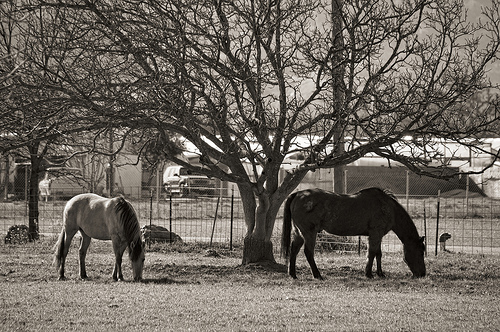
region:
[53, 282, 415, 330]
The grass on the ground is short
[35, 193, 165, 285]
The horse is eating grass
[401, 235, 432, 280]
The head of the horse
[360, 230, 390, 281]
The front legs of the horse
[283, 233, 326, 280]
The back legs of the horse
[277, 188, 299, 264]
The tail of the horse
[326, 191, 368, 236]
The stomach of the horse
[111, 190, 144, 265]
The mane of the horse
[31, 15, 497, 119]
The tree is large with no leaves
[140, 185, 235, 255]
The fence is made of metal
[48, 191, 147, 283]
light grey horse grazing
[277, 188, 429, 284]
dark brown horse grazing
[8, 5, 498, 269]
tree bare of leaves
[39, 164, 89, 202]
white pick up truck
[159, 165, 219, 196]
dark sport utility vehicle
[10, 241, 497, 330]
green grass in meadow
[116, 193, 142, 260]
dark hair on mane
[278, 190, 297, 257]
long dark horse hair tail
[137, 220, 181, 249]
boulder at grass edge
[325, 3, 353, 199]
tall flag pole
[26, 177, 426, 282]
two horses in field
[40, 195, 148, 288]
white horse in field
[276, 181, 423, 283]
dark horse in field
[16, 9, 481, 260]
tree with leafless branches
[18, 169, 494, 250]
fence behind the horses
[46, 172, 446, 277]
two horses grazing on grass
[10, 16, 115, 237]
tree on left side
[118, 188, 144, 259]
dark hair of white horse's mane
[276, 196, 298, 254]
dark hair of dark horse's tail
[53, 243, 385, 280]
legs of two horses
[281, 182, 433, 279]
a black horse grazing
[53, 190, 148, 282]
a grey horse grazing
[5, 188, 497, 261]
a long metal fence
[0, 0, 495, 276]
a large bare tree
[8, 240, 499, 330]
a green grassy field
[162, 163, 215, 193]
a parked SUV truck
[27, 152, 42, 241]
a black tree trunk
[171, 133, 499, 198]
a white building in distance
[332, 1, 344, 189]
a tall telephone pole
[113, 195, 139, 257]
a horse's mane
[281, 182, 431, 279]
A horse eating some grass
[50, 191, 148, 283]
A horse eating some grass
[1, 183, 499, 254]
A metal wire fence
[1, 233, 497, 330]
A grassy landscape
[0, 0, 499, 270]
A large leafless tree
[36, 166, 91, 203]
A parked light colored truck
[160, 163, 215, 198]
A parked light colored van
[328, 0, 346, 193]
A large wooden pole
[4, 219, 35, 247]
A small bush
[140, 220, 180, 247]
A large rock in the ground